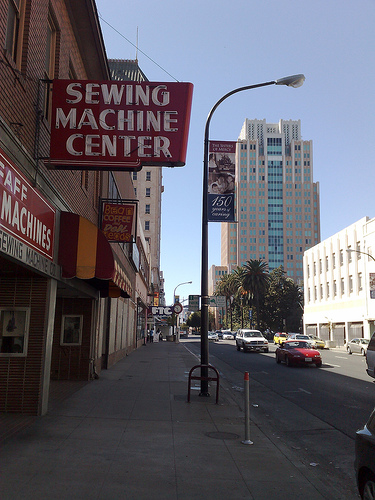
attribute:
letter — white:
[83, 79, 100, 106]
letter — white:
[99, 83, 124, 106]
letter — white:
[133, 82, 151, 106]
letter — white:
[149, 83, 169, 106]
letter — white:
[54, 106, 76, 129]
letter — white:
[75, 107, 97, 130]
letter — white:
[96, 106, 115, 130]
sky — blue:
[0, 1, 374, 328]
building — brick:
[0, 0, 99, 421]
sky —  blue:
[232, 22, 305, 65]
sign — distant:
[152, 302, 175, 317]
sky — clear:
[224, 11, 334, 58]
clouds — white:
[237, 32, 280, 51]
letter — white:
[117, 133, 137, 159]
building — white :
[301, 216, 373, 354]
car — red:
[274, 338, 322, 368]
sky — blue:
[96, 0, 365, 218]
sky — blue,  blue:
[92, 0, 373, 306]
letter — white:
[82, 134, 102, 156]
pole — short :
[242, 366, 255, 444]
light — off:
[272, 72, 305, 88]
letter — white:
[66, 131, 83, 160]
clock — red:
[172, 300, 184, 315]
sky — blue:
[309, 87, 361, 199]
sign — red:
[34, 71, 214, 172]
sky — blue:
[299, 27, 364, 65]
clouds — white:
[184, 51, 237, 84]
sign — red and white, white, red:
[42, 77, 194, 170]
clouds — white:
[172, 231, 195, 274]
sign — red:
[50, 85, 185, 158]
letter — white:
[63, 79, 84, 105]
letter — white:
[133, 132, 154, 158]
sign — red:
[54, 60, 187, 172]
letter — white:
[153, 135, 172, 157]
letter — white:
[51, 70, 191, 160]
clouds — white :
[114, 7, 266, 77]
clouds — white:
[184, 20, 293, 101]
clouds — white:
[292, 109, 346, 142]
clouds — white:
[308, 31, 373, 65]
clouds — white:
[285, 27, 329, 61]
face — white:
[168, 299, 185, 316]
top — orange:
[237, 369, 256, 383]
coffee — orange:
[97, 204, 132, 248]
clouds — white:
[327, 89, 361, 155]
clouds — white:
[325, 57, 365, 142]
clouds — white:
[336, 83, 366, 146]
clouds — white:
[170, 191, 191, 262]